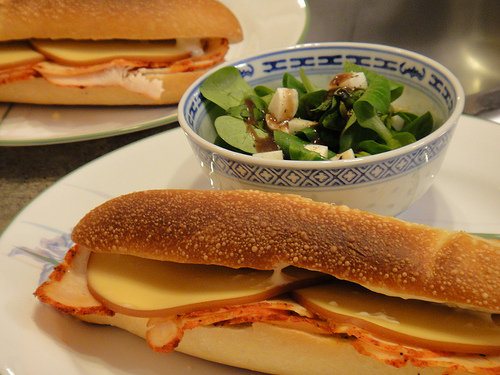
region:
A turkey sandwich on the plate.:
[86, 189, 488, 369]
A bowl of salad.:
[221, 62, 452, 182]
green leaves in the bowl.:
[230, 64, 405, 148]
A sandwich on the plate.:
[24, 7, 212, 99]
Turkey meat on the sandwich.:
[54, 257, 110, 321]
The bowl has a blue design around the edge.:
[330, 158, 447, 182]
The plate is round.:
[13, 90, 185, 218]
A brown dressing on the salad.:
[236, 91, 285, 138]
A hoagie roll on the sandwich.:
[103, 187, 498, 349]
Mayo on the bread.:
[257, 267, 303, 286]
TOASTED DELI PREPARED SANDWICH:
[36, 170, 489, 373]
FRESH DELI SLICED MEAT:
[129, 269, 207, 305]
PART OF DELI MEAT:
[346, 306, 413, 338]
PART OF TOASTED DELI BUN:
[144, 202, 271, 246]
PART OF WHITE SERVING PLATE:
[126, 154, 172, 182]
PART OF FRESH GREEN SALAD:
[214, 59, 379, 151]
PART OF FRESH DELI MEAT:
[63, 50, 133, 63]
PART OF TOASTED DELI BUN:
[25, 8, 141, 28]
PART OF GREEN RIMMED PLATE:
[45, 119, 102, 131]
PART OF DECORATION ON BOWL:
[331, 163, 381, 180]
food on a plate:
[83, 50, 495, 372]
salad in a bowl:
[202, 61, 429, 161]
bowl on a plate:
[167, 40, 467, 196]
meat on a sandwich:
[40, 246, 92, 320]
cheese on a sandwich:
[77, 250, 236, 319]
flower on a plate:
[25, 215, 62, 262]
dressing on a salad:
[245, 123, 276, 150]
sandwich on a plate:
[11, 5, 237, 95]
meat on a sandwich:
[57, 62, 158, 99]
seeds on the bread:
[237, 196, 292, 230]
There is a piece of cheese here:
[402, 298, 422, 360]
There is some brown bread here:
[354, 219, 364, 255]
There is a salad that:
[291, 124, 302, 140]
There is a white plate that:
[23, 318, 40, 353]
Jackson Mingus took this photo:
[175, 160, 247, 352]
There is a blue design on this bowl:
[390, 152, 400, 182]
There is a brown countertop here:
[16, 163, 27, 198]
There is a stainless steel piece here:
[459, 15, 482, 71]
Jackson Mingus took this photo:
[142, 72, 229, 238]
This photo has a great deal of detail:
[126, 82, 258, 359]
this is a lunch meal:
[15, 28, 489, 306]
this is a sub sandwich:
[106, 230, 458, 374]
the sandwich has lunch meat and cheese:
[93, 245, 291, 360]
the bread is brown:
[102, 193, 420, 352]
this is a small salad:
[198, 73, 498, 199]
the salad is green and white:
[205, 79, 461, 181]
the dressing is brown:
[236, 95, 319, 170]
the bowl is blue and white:
[165, 112, 420, 186]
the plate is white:
[44, 178, 199, 222]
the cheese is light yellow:
[101, 250, 251, 322]